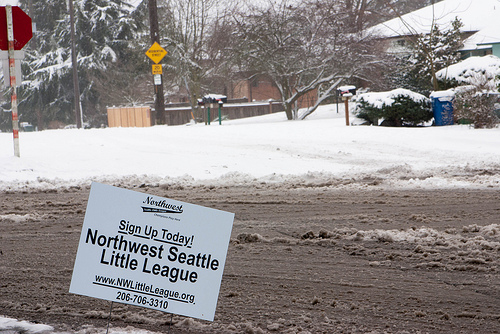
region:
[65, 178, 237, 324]
white sign with black letters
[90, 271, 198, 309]
phone number and website on sign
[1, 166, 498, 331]
muddy slush in road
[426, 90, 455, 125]
blue garbage can in bushes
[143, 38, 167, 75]
yellow signs with black letters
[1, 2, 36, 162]
back of red stop sign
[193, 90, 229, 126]
group of mailboxes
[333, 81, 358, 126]
snow covered mailbox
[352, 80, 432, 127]
snow covered bush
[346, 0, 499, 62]
part of snow covered house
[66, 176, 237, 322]
A white sign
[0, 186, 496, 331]
Dirty slushy snow on the roadway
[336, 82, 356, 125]
A black mailbox with snow on it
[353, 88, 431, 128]
A bush covered with snow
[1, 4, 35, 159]
The backside of a stop sign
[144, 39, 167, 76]
A yellow traffic sign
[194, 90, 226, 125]
A line of mailboxes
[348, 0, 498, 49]
The rooftop is covered with snow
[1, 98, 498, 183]
A blanket of snow covers the ground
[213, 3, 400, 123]
The tree has no leaves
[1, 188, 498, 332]
dirty snow on the road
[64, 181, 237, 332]
a small sign for Northwest Seattle Little League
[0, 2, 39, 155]
the back view of a stop sign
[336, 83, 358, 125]
a mailbox covered in snow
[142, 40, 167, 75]
a yellow warning sign on the wooden pole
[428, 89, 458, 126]
a blue recycling bin in front of the house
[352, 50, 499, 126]
a series of bushes covered in snow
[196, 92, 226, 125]
a row of mailboxes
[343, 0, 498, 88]
a house with a snow covered roof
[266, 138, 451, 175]
tracks from a car in the driveway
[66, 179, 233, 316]
white sign with black lettering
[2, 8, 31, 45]
red back of stop sign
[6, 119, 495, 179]
snow covered ground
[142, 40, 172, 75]
yellow signs with black lettering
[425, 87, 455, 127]
blue trashcan next to bushes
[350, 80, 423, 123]
bushes with tops covered in snow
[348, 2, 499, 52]
snow covered roofs of houses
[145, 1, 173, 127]
pole yellow signs are attached to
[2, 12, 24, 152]
pole stop sign is attached to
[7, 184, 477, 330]
road with snow slush on it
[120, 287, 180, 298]
writing on the sign.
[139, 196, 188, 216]
logo on the sign.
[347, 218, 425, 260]
snow in the street.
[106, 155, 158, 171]
snow on the ground.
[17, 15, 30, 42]
red paint on sign.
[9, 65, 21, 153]
pole supporting the sign.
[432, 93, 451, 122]
trash can near house.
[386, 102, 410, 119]
bush in the yard.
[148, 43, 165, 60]
sign on the pole.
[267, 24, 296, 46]
branches on the tree.